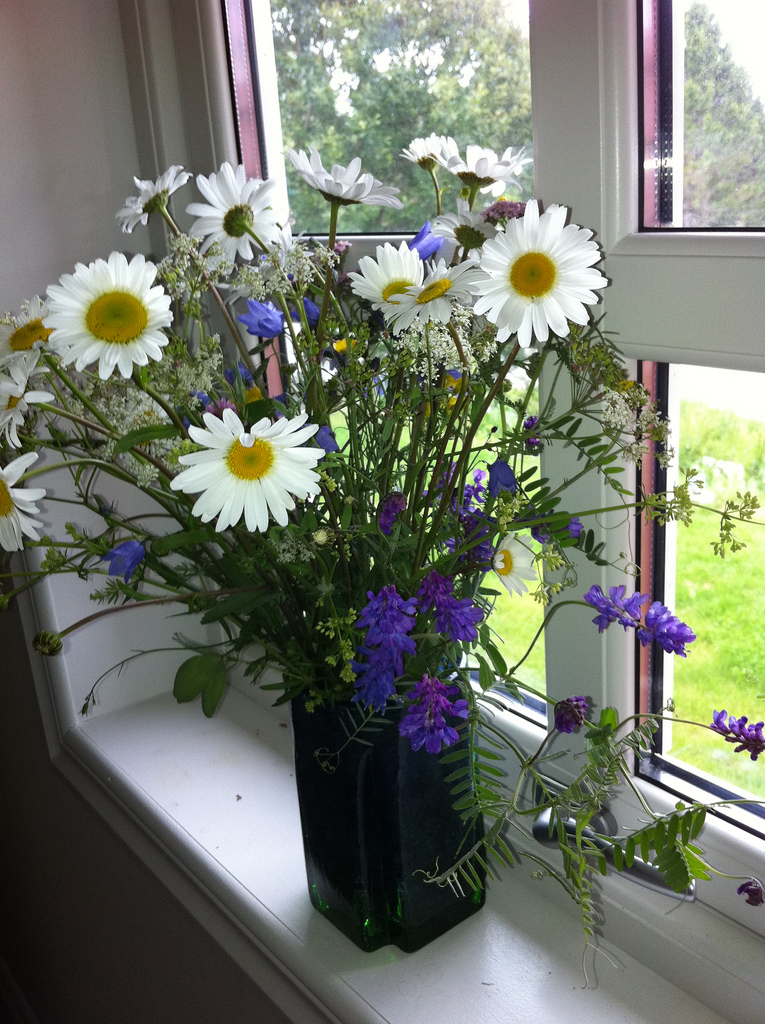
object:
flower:
[352, 586, 418, 712]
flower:
[399, 673, 471, 756]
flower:
[417, 569, 484, 641]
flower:
[583, 584, 696, 658]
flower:
[554, 695, 589, 733]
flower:
[169, 406, 326, 532]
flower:
[44, 250, 175, 381]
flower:
[468, 197, 608, 348]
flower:
[384, 258, 490, 337]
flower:
[347, 241, 424, 312]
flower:
[507, 249, 556, 299]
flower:
[415, 276, 449, 303]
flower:
[230, 436, 272, 480]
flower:
[86, 293, 147, 342]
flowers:
[168, 399, 337, 534]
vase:
[291, 688, 488, 953]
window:
[215, 0, 529, 239]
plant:
[0, 132, 765, 987]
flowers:
[350, 569, 483, 755]